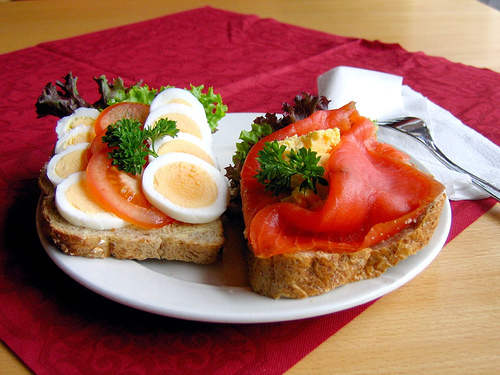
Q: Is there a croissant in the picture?
A: No, there are no croissants.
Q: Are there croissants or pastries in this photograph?
A: No, there are no croissants or pastries.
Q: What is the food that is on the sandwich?
A: The food is eggs.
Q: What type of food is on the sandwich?
A: The food is eggs.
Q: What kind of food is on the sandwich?
A: The food is eggs.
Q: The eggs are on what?
A: The eggs are on the sandwich.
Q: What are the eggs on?
A: The eggs are on the sandwich.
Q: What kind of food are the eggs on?
A: The eggs are on the sandwich.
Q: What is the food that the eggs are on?
A: The food is a sandwich.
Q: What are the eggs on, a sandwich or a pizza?
A: The eggs are on a sandwich.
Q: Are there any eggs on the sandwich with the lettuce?
A: Yes, there are eggs on the sandwich.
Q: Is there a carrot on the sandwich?
A: No, there are eggs on the sandwich.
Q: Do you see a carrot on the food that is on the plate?
A: No, there are eggs on the sandwich.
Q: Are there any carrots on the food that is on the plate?
A: No, there are eggs on the sandwich.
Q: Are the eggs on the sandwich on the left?
A: Yes, the eggs are on the sandwich.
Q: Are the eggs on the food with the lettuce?
A: Yes, the eggs are on the sandwich.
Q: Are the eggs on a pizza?
A: No, the eggs are on the sandwich.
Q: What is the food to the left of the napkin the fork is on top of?
A: The food is eggs.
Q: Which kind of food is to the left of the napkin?
A: The food is eggs.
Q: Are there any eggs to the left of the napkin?
A: Yes, there are eggs to the left of the napkin.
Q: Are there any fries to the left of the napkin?
A: No, there are eggs to the left of the napkin.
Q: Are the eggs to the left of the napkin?
A: Yes, the eggs are to the left of the napkin.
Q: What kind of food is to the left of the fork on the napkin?
A: The food is eggs.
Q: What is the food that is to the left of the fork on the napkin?
A: The food is eggs.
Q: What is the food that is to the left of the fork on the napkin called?
A: The food is eggs.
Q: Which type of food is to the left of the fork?
A: The food is eggs.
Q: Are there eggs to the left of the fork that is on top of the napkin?
A: Yes, there are eggs to the left of the fork.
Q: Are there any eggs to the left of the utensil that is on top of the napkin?
A: Yes, there are eggs to the left of the fork.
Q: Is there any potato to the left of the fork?
A: No, there are eggs to the left of the fork.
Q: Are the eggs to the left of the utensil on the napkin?
A: Yes, the eggs are to the left of the fork.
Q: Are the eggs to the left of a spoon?
A: No, the eggs are to the left of the fork.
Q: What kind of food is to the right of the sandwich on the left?
A: The food is eggs.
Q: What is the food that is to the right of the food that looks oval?
A: The food is eggs.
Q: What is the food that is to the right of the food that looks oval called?
A: The food is eggs.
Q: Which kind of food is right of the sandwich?
A: The food is eggs.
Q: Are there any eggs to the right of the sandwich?
A: Yes, there are eggs to the right of the sandwich.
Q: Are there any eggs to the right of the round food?
A: Yes, there are eggs to the right of the sandwich.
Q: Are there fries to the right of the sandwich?
A: No, there are eggs to the right of the sandwich.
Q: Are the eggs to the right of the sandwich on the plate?
A: Yes, the eggs are to the right of the sandwich.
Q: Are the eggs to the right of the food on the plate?
A: Yes, the eggs are to the right of the sandwich.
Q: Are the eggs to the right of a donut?
A: No, the eggs are to the right of the sandwich.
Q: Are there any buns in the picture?
A: No, there are no buns.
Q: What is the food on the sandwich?
A: The food is salmon.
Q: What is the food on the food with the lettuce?
A: The food is salmon.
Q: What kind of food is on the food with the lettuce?
A: The food is salmon.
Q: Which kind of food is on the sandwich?
A: The food is salmon.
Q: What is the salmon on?
A: The salmon is on the sandwich.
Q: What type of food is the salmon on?
A: The salmon is on the sandwich.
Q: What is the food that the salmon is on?
A: The food is a sandwich.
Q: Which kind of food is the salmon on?
A: The salmon is on the sandwich.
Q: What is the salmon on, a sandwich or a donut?
A: The salmon is on a sandwich.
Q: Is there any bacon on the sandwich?
A: No, there is salmon on the sandwich.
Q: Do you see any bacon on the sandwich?
A: No, there is salmon on the sandwich.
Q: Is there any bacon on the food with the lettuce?
A: No, there is salmon on the sandwich.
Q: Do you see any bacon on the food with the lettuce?
A: No, there is salmon on the sandwich.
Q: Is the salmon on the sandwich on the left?
A: Yes, the salmon is on the sandwich.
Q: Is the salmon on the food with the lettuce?
A: Yes, the salmon is on the sandwich.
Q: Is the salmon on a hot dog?
A: No, the salmon is on the sandwich.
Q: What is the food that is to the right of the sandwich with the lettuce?
A: The food is salmon.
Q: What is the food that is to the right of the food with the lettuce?
A: The food is salmon.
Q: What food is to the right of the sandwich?
A: The food is salmon.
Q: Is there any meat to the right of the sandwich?
A: No, there is salmon to the right of the sandwich.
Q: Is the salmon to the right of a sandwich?
A: Yes, the salmon is to the right of a sandwich.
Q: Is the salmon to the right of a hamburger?
A: No, the salmon is to the right of a sandwich.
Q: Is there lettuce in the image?
A: Yes, there is lettuce.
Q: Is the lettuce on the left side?
A: Yes, the lettuce is on the left of the image.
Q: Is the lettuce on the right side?
A: No, the lettuce is on the left of the image.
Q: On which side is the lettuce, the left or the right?
A: The lettuce is on the left of the image.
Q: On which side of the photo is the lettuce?
A: The lettuce is on the left of the image.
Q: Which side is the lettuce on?
A: The lettuce is on the left of the image.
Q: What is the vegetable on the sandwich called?
A: The vegetable is lettuce.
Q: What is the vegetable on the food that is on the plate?
A: The vegetable is lettuce.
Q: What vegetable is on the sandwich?
A: The vegetable is lettuce.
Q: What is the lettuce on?
A: The lettuce is on the sandwich.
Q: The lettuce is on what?
A: The lettuce is on the sandwich.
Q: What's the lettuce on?
A: The lettuce is on the sandwich.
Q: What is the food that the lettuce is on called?
A: The food is a sandwich.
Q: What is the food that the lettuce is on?
A: The food is a sandwich.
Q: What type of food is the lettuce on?
A: The lettuce is on the sandwich.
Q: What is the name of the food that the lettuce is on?
A: The food is a sandwich.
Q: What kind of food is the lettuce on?
A: The lettuce is on the sandwich.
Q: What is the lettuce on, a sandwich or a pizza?
A: The lettuce is on a sandwich.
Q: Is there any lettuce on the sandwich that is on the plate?
A: Yes, there is lettuce on the sandwich.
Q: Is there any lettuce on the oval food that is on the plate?
A: Yes, there is lettuce on the sandwich.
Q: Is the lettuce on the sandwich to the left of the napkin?
A: Yes, the lettuce is on the sandwich.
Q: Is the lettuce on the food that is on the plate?
A: Yes, the lettuce is on the sandwich.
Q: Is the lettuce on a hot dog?
A: No, the lettuce is on the sandwich.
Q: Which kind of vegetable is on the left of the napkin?
A: The vegetable is lettuce.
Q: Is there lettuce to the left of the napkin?
A: Yes, there is lettuce to the left of the napkin.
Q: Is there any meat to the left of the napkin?
A: No, there is lettuce to the left of the napkin.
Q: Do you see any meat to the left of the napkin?
A: No, there is lettuce to the left of the napkin.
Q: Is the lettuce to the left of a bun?
A: No, the lettuce is to the left of the napkin.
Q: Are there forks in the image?
A: Yes, there is a fork.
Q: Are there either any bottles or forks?
A: Yes, there is a fork.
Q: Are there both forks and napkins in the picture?
A: Yes, there are both a fork and a napkin.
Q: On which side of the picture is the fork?
A: The fork is on the right of the image.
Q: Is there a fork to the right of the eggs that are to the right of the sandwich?
A: Yes, there is a fork to the right of the eggs.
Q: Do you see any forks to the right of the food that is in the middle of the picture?
A: Yes, there is a fork to the right of the eggs.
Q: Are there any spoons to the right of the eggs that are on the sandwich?
A: No, there is a fork to the right of the eggs.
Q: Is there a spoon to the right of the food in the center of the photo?
A: No, there is a fork to the right of the eggs.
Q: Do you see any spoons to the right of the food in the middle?
A: No, there is a fork to the right of the eggs.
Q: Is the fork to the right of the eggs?
A: Yes, the fork is to the right of the eggs.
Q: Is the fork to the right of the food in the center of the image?
A: Yes, the fork is to the right of the eggs.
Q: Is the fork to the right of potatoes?
A: No, the fork is to the right of the eggs.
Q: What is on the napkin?
A: The fork is on the napkin.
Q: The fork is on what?
A: The fork is on the napkin.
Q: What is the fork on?
A: The fork is on the napkin.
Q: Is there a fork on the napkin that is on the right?
A: Yes, there is a fork on the napkin.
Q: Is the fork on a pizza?
A: No, the fork is on the napkin.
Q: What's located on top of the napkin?
A: The fork is on top of the napkin.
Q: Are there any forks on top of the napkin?
A: Yes, there is a fork on top of the napkin.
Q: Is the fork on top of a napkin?
A: Yes, the fork is on top of a napkin.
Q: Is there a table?
A: Yes, there is a table.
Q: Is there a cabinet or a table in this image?
A: Yes, there is a table.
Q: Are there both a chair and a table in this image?
A: No, there is a table but no chairs.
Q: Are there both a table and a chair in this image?
A: No, there is a table but no chairs.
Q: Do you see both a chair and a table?
A: No, there is a table but no chairs.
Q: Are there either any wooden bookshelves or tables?
A: Yes, there is a wood table.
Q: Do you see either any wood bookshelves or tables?
A: Yes, there is a wood table.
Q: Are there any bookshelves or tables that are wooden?
A: Yes, the table is wooden.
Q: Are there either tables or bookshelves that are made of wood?
A: Yes, the table is made of wood.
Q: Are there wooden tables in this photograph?
A: Yes, there is a wood table.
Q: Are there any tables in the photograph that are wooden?
A: Yes, there is a table that is wooden.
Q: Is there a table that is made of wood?
A: Yes, there is a table that is made of wood.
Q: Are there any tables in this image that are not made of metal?
A: Yes, there is a table that is made of wood.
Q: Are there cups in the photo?
A: No, there are no cups.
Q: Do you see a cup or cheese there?
A: No, there are no cups or cheese.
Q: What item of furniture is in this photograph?
A: The piece of furniture is a table.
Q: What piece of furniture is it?
A: The piece of furniture is a table.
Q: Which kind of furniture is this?
A: This is a table.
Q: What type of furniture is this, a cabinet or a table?
A: This is a table.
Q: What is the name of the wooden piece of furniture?
A: The piece of furniture is a table.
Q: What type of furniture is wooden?
A: The furniture is a table.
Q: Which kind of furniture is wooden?
A: The furniture is a table.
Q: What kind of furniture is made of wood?
A: The furniture is a table.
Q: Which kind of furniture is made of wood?
A: The furniture is a table.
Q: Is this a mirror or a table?
A: This is a table.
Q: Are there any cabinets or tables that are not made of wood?
A: No, there is a table but it is made of wood.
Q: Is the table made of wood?
A: Yes, the table is made of wood.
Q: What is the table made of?
A: The table is made of wood.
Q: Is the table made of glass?
A: No, the table is made of wood.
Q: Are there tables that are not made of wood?
A: No, there is a table but it is made of wood.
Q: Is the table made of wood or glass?
A: The table is made of wood.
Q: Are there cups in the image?
A: No, there are no cups.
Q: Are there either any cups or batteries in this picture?
A: No, there are no cups or batteries.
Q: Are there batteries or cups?
A: No, there are no cups or batteries.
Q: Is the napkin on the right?
A: Yes, the napkin is on the right of the image.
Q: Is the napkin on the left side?
A: No, the napkin is on the right of the image.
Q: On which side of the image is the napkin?
A: The napkin is on the right of the image.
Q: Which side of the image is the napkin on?
A: The napkin is on the right of the image.